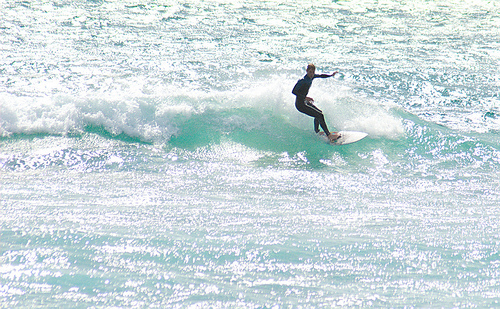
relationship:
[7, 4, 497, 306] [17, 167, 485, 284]
water covering surface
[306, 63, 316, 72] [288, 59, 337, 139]
hair on man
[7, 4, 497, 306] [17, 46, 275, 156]
water has waves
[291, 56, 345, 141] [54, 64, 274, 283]
man on water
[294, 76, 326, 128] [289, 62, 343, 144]
wet suit on man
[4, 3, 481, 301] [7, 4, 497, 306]
ripples on water